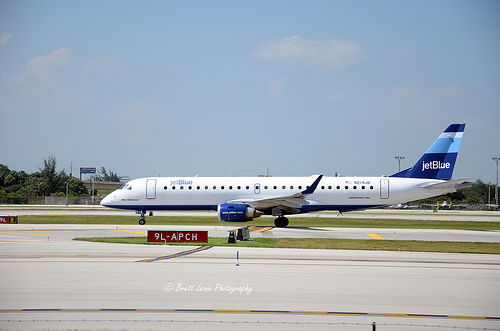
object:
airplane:
[100, 123, 477, 228]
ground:
[1, 203, 500, 330]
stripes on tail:
[410, 123, 465, 179]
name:
[165, 177, 193, 186]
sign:
[145, 230, 202, 243]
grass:
[0, 214, 500, 254]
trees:
[1, 165, 90, 203]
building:
[80, 175, 127, 198]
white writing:
[223, 208, 245, 214]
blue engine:
[218, 201, 256, 222]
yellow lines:
[363, 229, 385, 241]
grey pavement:
[0, 199, 500, 329]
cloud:
[0, 1, 500, 181]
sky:
[1, 3, 498, 177]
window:
[162, 185, 169, 190]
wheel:
[271, 217, 288, 226]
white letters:
[153, 232, 203, 241]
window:
[370, 184, 376, 190]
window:
[361, 185, 367, 190]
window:
[351, 185, 356, 190]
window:
[344, 185, 349, 192]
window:
[336, 184, 341, 189]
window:
[320, 185, 328, 193]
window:
[328, 187, 332, 190]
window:
[299, 184, 305, 189]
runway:
[0, 205, 498, 330]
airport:
[0, 1, 500, 330]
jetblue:
[169, 178, 200, 186]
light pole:
[492, 151, 500, 207]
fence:
[28, 195, 106, 208]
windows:
[204, 182, 213, 190]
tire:
[139, 217, 148, 225]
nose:
[97, 186, 122, 210]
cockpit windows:
[118, 184, 134, 191]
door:
[145, 179, 158, 199]